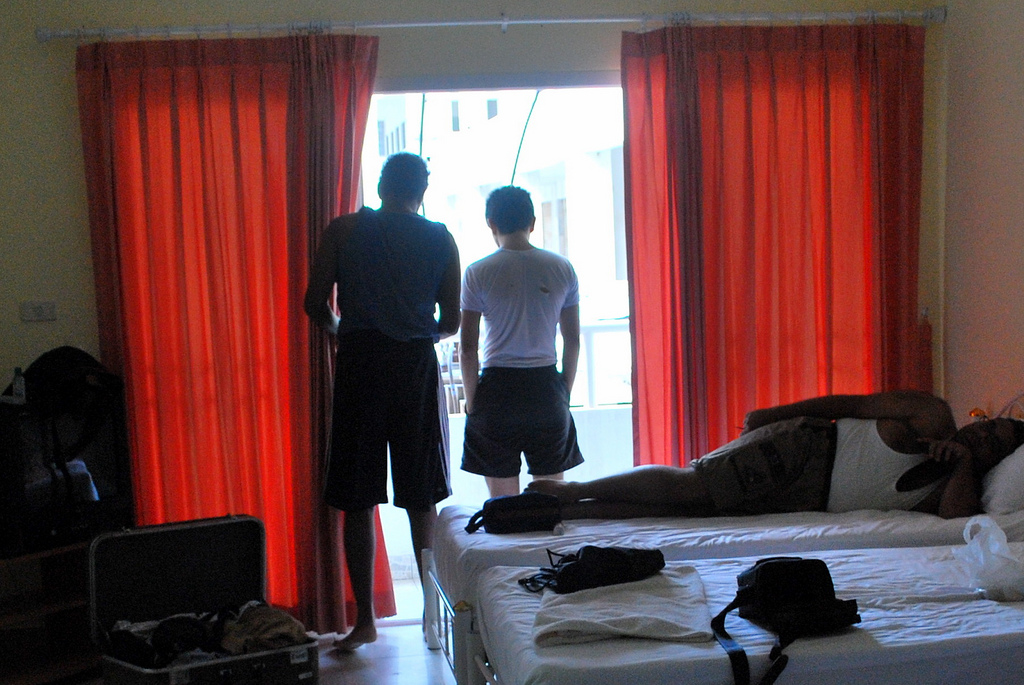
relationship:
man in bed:
[523, 390, 1024, 520] [427, 502, 1020, 680]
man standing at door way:
[301, 153, 463, 651] [403, 106, 656, 459]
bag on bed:
[686, 556, 857, 680] [861, 517, 1002, 623]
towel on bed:
[535, 569, 717, 639] [487, 542, 1021, 681]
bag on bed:
[709, 557, 860, 685] [504, 536, 1019, 657]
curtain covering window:
[623, 19, 930, 467] [355, 82, 636, 547]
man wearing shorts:
[292, 145, 465, 649] [316, 336, 457, 499]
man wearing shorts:
[491, 389, 1012, 511] [681, 400, 831, 511]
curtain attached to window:
[72, 46, 956, 470] [173, 104, 794, 459]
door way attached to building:
[354, 86, 638, 584] [39, 20, 988, 572]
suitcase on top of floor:
[61, 482, 351, 677] [262, 616, 470, 683]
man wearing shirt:
[458, 185, 586, 499] [471, 253, 577, 370]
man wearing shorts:
[459, 176, 596, 499] [458, 355, 592, 466]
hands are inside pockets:
[441, 333, 582, 409] [452, 355, 576, 427]